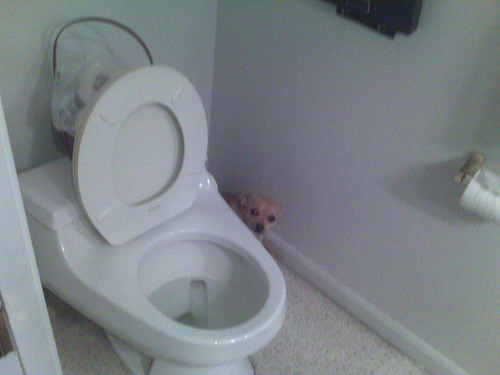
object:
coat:
[215, 167, 294, 235]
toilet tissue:
[456, 168, 498, 226]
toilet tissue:
[75, 62, 120, 106]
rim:
[125, 225, 278, 341]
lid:
[69, 66, 209, 250]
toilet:
[110, 213, 291, 373]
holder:
[447, 147, 482, 199]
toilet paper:
[462, 159, 497, 226]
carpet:
[42, 238, 428, 373]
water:
[146, 277, 238, 327]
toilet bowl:
[18, 64, 290, 373]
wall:
[219, 7, 497, 352]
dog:
[230, 185, 292, 240]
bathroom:
[11, 5, 486, 366]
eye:
[248, 207, 258, 214]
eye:
[266, 213, 276, 225]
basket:
[53, 17, 154, 159]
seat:
[54, 48, 318, 357]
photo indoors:
[28, 13, 488, 331]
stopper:
[97, 107, 119, 133]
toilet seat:
[61, 130, 146, 236]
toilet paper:
[43, 41, 144, 88]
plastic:
[39, 34, 75, 80]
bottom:
[83, 73, 201, 229]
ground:
[29, 214, 442, 371]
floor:
[37, 215, 446, 372]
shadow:
[441, 12, 499, 159]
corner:
[193, 6, 239, 184]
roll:
[454, 162, 499, 226]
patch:
[315, 331, 336, 356]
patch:
[282, 340, 302, 363]